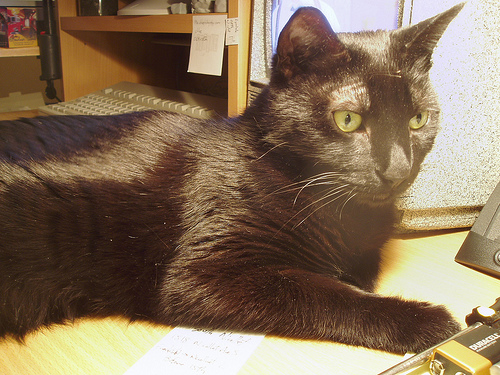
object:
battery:
[426, 324, 499, 375]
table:
[395, 237, 473, 293]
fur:
[37, 119, 184, 207]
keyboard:
[36, 81, 228, 118]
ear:
[268, 5, 347, 80]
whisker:
[242, 171, 356, 254]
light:
[447, 28, 498, 131]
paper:
[186, 15, 228, 77]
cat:
[0, 1, 466, 357]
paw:
[399, 300, 462, 355]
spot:
[176, 157, 279, 241]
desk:
[62, 320, 157, 375]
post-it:
[184, 15, 241, 76]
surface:
[44, 337, 202, 372]